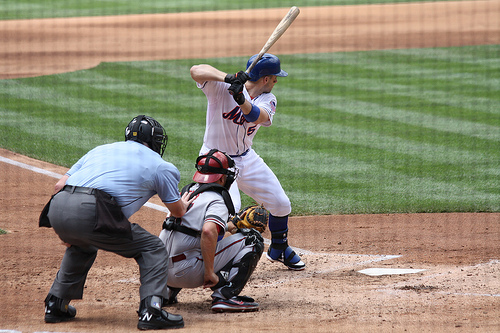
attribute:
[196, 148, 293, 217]
pants — white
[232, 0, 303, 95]
bat — baseball, wooden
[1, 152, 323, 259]
foul line — white, for foul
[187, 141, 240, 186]
baseball helmet — red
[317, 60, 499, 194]
grass — green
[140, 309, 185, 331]
umpire's shoe — New Balance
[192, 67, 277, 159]
shirt — white, blue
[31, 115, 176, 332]
umpire — call-making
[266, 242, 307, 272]
shoes — blue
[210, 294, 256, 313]
cleat — black, baseball